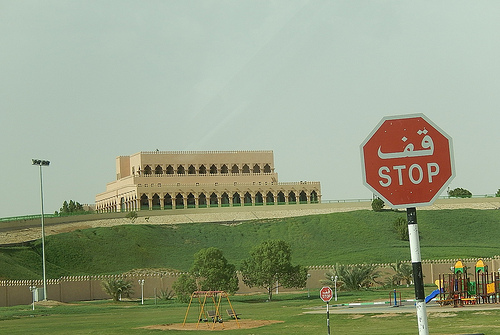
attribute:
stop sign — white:
[365, 104, 456, 205]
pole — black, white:
[405, 201, 433, 334]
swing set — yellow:
[182, 288, 237, 333]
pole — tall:
[36, 165, 49, 304]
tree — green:
[237, 231, 302, 302]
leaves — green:
[253, 242, 282, 264]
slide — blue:
[424, 286, 442, 303]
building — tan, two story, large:
[107, 147, 322, 205]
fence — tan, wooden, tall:
[4, 255, 499, 303]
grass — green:
[27, 294, 490, 333]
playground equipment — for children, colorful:
[426, 263, 498, 314]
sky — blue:
[1, 2, 500, 215]